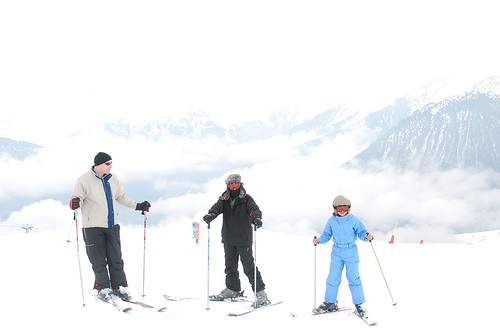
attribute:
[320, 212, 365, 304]
outfit — blue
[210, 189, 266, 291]
outfit — black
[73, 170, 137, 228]
coat — tan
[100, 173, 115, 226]
shirt — blue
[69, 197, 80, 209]
glove — red, black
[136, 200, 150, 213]
glove — red, black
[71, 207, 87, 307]
pole — red, white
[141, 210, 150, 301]
pole — red, white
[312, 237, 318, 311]
pole — black, white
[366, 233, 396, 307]
pole — black, white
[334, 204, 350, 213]
goggles — orange, black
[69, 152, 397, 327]
group — skiing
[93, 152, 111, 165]
hat — black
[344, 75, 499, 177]
mountain — blue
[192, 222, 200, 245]
flag — pink, blue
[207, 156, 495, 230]
cloud — white